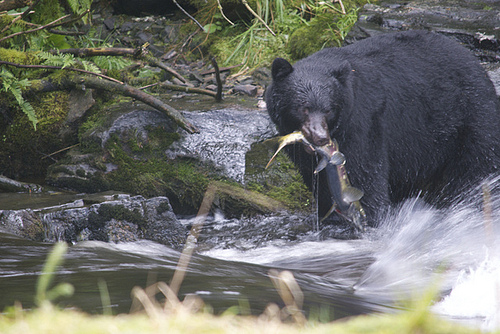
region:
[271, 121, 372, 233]
a dead fish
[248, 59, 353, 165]
a black bear with fish in mouth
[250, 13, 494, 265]
a black bear in a river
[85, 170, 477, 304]
water in a river is splashing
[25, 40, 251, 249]
mossy rocks on the side of river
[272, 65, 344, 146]
black bear looks at water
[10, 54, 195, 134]
broken tree branches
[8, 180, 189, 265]
rock jutting out of the river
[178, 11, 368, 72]
mossy tree roots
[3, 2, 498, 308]
bear fishing in a river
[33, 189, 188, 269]
a rock in water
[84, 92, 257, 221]
a rock in water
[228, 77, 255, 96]
a rock in water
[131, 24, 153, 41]
a rock in water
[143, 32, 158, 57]
a rock in water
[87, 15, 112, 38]
a rock in water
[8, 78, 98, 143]
a rock in water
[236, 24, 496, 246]
a black bear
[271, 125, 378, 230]
a black fish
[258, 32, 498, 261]
a black bear with a fish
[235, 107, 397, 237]
The bear has a fish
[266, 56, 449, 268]
This bear is black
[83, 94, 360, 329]
The water is flowing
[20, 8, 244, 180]
There are branches in the back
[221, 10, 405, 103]
the vegetation is green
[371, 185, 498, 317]
The water is moving quick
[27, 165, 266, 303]
There are rocks in the water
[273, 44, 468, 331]
The bear has food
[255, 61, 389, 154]
The bear has two ears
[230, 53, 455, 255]
The bear is large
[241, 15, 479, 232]
A wet black bear is standing in a river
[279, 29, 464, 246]
The black bear has a fish in its mouth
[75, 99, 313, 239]
Green moss grows on the rocks near the water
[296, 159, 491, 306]
The current of the water sends up a spray of water when it hits the rocks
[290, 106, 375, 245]
The fish is long, thin, grey and beige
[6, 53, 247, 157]
Branches hang over the rocks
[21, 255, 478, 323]
There is grass on one side of the river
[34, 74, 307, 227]
The rocks are dark grey and glistening from the water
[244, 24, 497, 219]
The bear looks into the water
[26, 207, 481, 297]
The water is moving fast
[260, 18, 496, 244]
a black bear eating a fish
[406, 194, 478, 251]
water spraying into the air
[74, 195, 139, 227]
dark green moss on a rock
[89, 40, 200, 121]
broken tree branches in the water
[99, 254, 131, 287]
dark brown river water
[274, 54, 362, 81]
black ears on a head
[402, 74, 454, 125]
wet black fur on a body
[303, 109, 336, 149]
a brown snout on a face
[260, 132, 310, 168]
the tail of a fish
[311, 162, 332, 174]
a gray fin on a fish